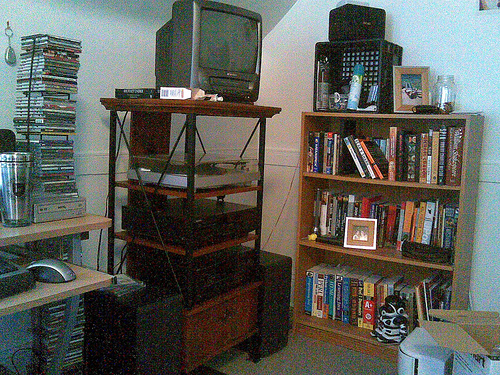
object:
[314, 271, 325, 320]
books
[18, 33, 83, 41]
cds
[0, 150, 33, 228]
cup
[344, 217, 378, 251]
picture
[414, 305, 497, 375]
box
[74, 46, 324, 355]
center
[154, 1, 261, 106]
tv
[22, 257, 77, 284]
mouse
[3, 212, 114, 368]
desk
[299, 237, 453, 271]
shelf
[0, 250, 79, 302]
computer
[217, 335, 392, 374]
ground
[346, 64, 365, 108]
freshener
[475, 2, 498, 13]
window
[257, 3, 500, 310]
wall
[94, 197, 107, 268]
cord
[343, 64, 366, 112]
can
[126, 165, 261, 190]
player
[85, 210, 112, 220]
edge